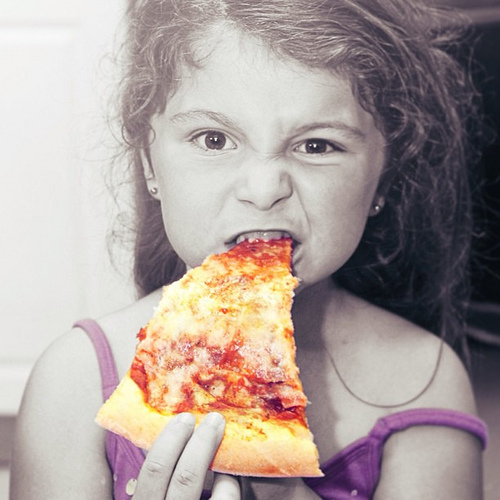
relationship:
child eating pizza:
[9, 0, 486, 499] [129, 248, 312, 461]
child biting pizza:
[9, 0, 486, 499] [135, 251, 327, 497]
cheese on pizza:
[168, 322, 234, 359] [146, 261, 321, 462]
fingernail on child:
[170, 409, 194, 428] [95, 63, 406, 441]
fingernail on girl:
[195, 405, 225, 430] [94, 57, 394, 463]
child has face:
[9, 0, 486, 499] [140, 20, 387, 298]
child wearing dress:
[9, 0, 486, 499] [74, 316, 488, 498]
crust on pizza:
[91, 373, 326, 480] [95, 241, 326, 479]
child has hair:
[9, 0, 486, 499] [80, 1, 483, 381]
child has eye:
[9, 0, 486, 499] [288, 132, 351, 158]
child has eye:
[9, 0, 486, 499] [186, 124, 242, 154]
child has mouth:
[9, 0, 486, 499] [218, 225, 304, 263]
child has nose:
[9, 0, 486, 499] [231, 154, 293, 212]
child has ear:
[9, 0, 486, 499] [368, 150, 394, 218]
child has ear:
[9, 0, 486, 499] [137, 144, 164, 201]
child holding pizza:
[9, 0, 486, 499] [95, 241, 326, 479]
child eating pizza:
[9, 0, 486, 499] [95, 241, 326, 479]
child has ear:
[9, 0, 486, 499] [139, 148, 159, 201]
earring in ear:
[148, 186, 159, 196] [139, 148, 159, 201]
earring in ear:
[370, 204, 380, 215] [367, 166, 391, 218]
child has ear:
[9, 0, 486, 499] [367, 166, 391, 218]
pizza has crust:
[95, 241, 326, 479] [91, 373, 326, 480]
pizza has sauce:
[95, 241, 326, 479] [131, 326, 310, 426]